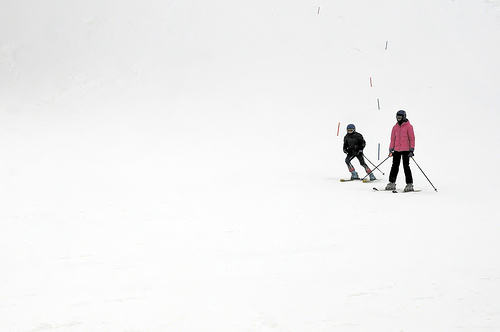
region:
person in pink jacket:
[380, 100, 426, 190]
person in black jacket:
[325, 111, 380, 186]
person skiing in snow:
[325, 111, 375, 186]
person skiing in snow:
[375, 95, 427, 200]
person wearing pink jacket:
[378, 103, 433, 205]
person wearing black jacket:
[334, 117, 382, 188]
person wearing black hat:
[384, 104, 430, 204]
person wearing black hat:
[334, 114, 378, 191]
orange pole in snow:
[329, 110, 346, 145]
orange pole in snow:
[361, 67, 378, 96]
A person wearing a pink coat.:
[390, 108, 414, 196]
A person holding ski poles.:
[362, 108, 438, 189]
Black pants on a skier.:
[389, 148, 411, 183]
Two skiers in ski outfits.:
[332, 107, 438, 198]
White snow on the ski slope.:
[89, 55, 325, 327]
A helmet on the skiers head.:
[389, 109, 409, 121]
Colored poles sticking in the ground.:
[360, 31, 395, 161]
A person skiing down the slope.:
[338, 119, 377, 184]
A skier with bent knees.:
[340, 120, 377, 197]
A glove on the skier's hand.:
[357, 147, 365, 157]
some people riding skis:
[322, 111, 448, 211]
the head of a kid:
[391, 108, 406, 122]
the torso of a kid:
[385, 121, 421, 151]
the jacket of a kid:
[388, 126, 419, 151]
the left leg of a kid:
[395, 151, 416, 184]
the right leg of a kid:
[376, 155, 401, 182]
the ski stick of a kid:
[407, 155, 442, 187]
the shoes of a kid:
[381, 178, 417, 198]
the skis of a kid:
[367, 177, 412, 202]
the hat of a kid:
[344, 121, 359, 130]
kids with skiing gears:
[322, 91, 439, 208]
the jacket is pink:
[379, 121, 420, 154]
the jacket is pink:
[384, 127, 431, 173]